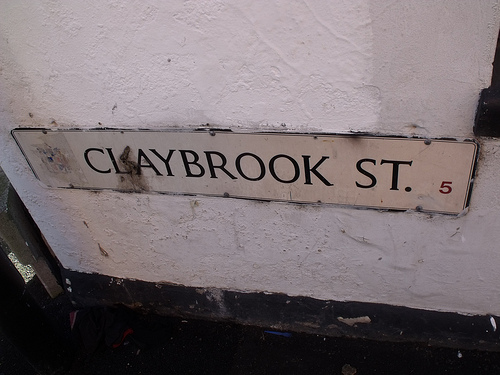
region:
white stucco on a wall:
[164, 6, 343, 51]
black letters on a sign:
[84, 132, 415, 199]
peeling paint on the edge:
[329, 299, 386, 340]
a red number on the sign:
[431, 164, 471, 209]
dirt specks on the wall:
[76, 201, 121, 263]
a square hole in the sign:
[37, 144, 64, 179]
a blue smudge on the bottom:
[263, 322, 295, 339]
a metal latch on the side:
[5, 251, 42, 280]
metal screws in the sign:
[203, 123, 440, 151]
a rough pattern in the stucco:
[254, 25, 352, 102]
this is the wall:
[166, 198, 269, 288]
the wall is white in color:
[332, 203, 380, 292]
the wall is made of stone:
[87, 215, 277, 280]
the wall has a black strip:
[176, 286, 249, 318]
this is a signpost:
[17, 127, 482, 212]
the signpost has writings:
[80, 141, 416, 196]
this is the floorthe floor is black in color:
[78, 317, 174, 365]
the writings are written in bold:
[133, 145, 334, 191]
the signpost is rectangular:
[25, 126, 475, 213]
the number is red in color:
[434, 176, 453, 207]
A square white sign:
[9, 105, 483, 260]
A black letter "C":
[80, 141, 109, 183]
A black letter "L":
[103, 140, 134, 189]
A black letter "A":
[135, 145, 161, 190]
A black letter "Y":
[148, 143, 178, 186]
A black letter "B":
[176, 141, 206, 184]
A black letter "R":
[202, 143, 239, 189]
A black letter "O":
[225, 144, 267, 188]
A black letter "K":
[302, 144, 333, 205]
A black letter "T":
[381, 147, 414, 205]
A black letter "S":
[349, 148, 381, 193]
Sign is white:
[0, 114, 486, 234]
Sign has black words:
[4, 119, 491, 221]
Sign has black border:
[1, 113, 490, 237]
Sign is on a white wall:
[1, 6, 498, 288]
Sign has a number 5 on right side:
[351, 127, 491, 238]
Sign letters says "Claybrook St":
[7, 111, 491, 236]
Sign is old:
[1, 116, 498, 228]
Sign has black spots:
[96, 111, 176, 217]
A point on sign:
[396, 173, 421, 202]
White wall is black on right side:
[444, 28, 498, 148]